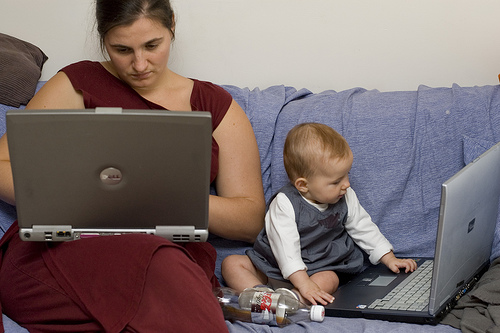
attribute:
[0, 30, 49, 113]
pillow — gray, brown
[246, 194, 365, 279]
dress — denim, red, gray, white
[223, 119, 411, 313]
baby — playing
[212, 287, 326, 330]
bottle — empty, plastic, laying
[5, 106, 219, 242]
computer — gray, silver, dell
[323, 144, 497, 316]
laptop — gray, silver, open, grey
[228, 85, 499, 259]
blanket — blue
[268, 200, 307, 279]
sleeve — white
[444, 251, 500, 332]
blanket — gray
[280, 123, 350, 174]
hair — brown, golden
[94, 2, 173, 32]
hair — brown, dark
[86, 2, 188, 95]
woman — looking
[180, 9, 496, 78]
wall — grey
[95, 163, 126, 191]
logo — dell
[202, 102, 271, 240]
arm — human